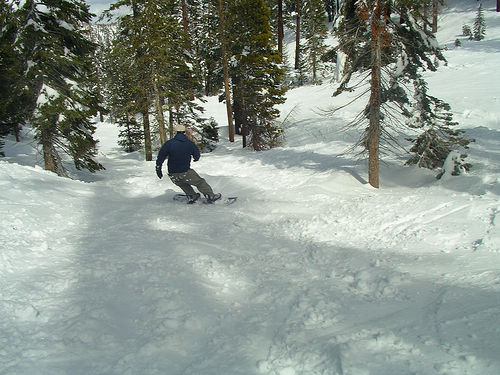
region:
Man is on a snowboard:
[152, 119, 237, 209]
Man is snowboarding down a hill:
[153, 120, 237, 209]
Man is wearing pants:
[165, 169, 215, 197]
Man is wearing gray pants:
[164, 168, 213, 198]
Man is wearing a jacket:
[155, 136, 199, 176]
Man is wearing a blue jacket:
[155, 135, 198, 172]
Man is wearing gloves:
[154, 160, 164, 178]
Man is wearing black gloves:
[150, 163, 165, 178]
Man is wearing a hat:
[172, 120, 190, 133]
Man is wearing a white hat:
[172, 121, 187, 135]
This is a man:
[81, 126, 279, 318]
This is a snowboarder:
[114, 113, 228, 243]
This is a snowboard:
[143, 177, 241, 227]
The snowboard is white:
[138, 166, 239, 217]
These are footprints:
[263, 230, 348, 311]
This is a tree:
[342, 88, 437, 199]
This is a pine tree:
[44, 37, 96, 111]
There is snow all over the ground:
[133, 245, 196, 312]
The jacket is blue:
[153, 132, 200, 177]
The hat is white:
[158, 108, 188, 128]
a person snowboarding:
[132, 84, 350, 274]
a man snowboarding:
[114, 115, 347, 297]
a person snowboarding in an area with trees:
[21, 8, 491, 323]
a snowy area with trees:
[0, 19, 490, 283]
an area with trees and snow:
[33, 3, 499, 340]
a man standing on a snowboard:
[127, 88, 384, 304]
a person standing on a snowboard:
[122, 101, 249, 283]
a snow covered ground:
[165, 191, 477, 373]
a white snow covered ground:
[203, 216, 425, 373]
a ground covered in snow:
[205, 220, 425, 350]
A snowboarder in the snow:
[156, 131, 233, 204]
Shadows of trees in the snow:
[12, 185, 498, 370]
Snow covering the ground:
[6, 5, 498, 373]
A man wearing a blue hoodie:
[151, 126, 201, 173]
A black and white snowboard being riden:
[173, 188, 236, 208]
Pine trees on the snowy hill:
[0, 0, 449, 180]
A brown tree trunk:
[360, 10, 389, 187]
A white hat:
[174, 122, 187, 132]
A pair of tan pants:
[169, 171, 211, 197]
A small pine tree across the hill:
[471, 2, 486, 43]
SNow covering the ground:
[10, 308, 59, 370]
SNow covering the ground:
[78, 323, 117, 355]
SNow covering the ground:
[182, 318, 254, 369]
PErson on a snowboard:
[139, 98, 245, 220]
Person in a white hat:
[131, 99, 258, 281]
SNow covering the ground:
[404, 229, 434, 281]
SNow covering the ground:
[288, 236, 355, 313]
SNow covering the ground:
[208, 224, 264, 288]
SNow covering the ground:
[73, 195, 140, 260]